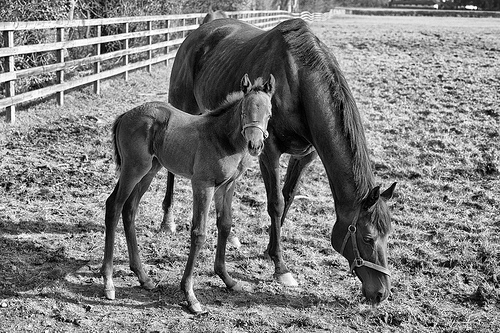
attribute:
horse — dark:
[162, 15, 412, 305]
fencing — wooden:
[5, 3, 287, 148]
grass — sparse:
[0, 15, 498, 332]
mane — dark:
[278, 17, 395, 233]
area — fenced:
[42, 15, 497, 328]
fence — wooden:
[18, 3, 199, 92]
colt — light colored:
[101, 70, 282, 315]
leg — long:
[214, 176, 241, 290]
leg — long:
[95, 154, 152, 303]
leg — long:
[177, 173, 216, 313]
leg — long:
[121, 155, 163, 295]